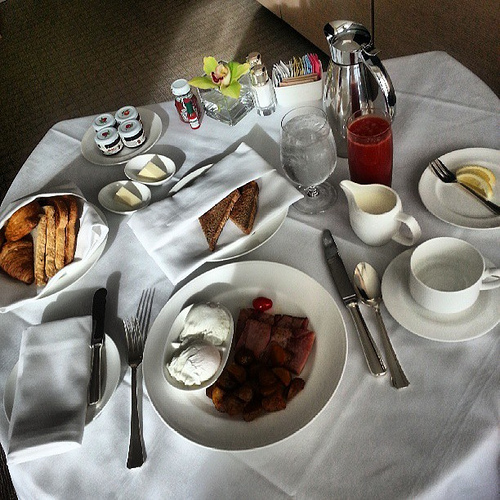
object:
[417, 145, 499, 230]
plate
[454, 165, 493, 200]
lemon slice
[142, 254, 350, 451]
plate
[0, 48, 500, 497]
table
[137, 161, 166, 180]
butter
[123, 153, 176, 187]
plate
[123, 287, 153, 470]
fork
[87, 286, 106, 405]
knife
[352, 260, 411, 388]
spoon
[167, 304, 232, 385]
eggs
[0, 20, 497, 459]
meal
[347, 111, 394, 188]
glass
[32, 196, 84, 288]
toast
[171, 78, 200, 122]
bottle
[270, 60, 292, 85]
sugar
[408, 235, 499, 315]
cup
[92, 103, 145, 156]
jellies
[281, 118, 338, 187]
water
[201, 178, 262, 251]
toast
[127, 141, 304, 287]
napkin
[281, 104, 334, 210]
glass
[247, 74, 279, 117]
shaker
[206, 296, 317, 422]
food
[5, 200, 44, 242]
bread